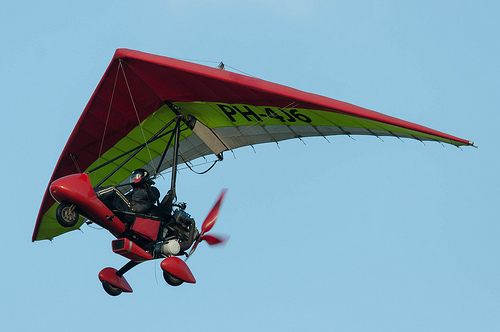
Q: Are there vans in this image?
A: No, there are no vans.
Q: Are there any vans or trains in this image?
A: No, there are no vans or trains.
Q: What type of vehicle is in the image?
A: The vehicle is a car.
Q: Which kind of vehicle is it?
A: The vehicle is a car.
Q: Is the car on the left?
A: Yes, the car is on the left of the image.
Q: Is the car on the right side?
A: No, the car is on the left of the image.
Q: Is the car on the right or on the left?
A: The car is on the left of the image.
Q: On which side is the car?
A: The car is on the left of the image.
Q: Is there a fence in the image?
A: No, there are no fences.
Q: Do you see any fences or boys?
A: No, there are no fences or boys.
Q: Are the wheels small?
A: Yes, the wheels are small.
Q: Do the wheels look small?
A: Yes, the wheels are small.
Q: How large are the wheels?
A: The wheels are small.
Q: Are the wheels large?
A: No, the wheels are small.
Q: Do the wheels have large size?
A: No, the wheels are small.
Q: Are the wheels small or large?
A: The wheels are small.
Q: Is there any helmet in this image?
A: Yes, there is a helmet.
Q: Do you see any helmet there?
A: Yes, there is a helmet.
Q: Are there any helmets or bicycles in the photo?
A: Yes, there is a helmet.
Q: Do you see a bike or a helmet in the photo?
A: Yes, there is a helmet.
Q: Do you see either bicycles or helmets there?
A: Yes, there is a helmet.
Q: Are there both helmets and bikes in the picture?
A: No, there is a helmet but no bikes.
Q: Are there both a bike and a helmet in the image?
A: No, there is a helmet but no bikes.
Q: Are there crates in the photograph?
A: No, there are no crates.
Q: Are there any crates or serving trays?
A: No, there are no crates or serving trays.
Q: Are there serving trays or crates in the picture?
A: No, there are no crates or serving trays.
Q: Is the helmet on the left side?
A: Yes, the helmet is on the left of the image.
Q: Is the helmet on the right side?
A: No, the helmet is on the left of the image.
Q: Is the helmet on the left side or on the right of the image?
A: The helmet is on the left of the image.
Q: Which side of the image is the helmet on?
A: The helmet is on the left of the image.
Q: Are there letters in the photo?
A: Yes, there are letters.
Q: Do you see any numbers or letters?
A: Yes, there are letters.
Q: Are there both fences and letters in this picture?
A: No, there are letters but no fences.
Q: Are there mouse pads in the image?
A: No, there are no mouse pads.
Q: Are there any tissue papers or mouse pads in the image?
A: No, there are no mouse pads or tissue papers.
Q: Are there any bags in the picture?
A: No, there are no bags.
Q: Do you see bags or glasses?
A: No, there are no bags or glasses.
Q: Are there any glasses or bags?
A: No, there are no bags or glasses.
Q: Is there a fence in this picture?
A: No, there are no fences.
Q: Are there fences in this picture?
A: No, there are no fences.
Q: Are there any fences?
A: No, there are no fences.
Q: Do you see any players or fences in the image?
A: No, there are no fences or players.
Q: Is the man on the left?
A: Yes, the man is on the left of the image.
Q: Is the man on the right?
A: No, the man is on the left of the image.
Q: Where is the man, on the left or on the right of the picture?
A: The man is on the left of the image.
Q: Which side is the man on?
A: The man is on the left of the image.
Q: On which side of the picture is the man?
A: The man is on the left of the image.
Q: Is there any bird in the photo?
A: No, there are no birds.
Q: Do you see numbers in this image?
A: Yes, there are numbers.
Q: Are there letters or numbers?
A: Yes, there are numbers.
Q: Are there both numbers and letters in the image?
A: Yes, there are both numbers and letters.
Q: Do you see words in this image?
A: No, there are no words.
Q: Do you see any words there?
A: No, there are no words.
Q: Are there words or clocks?
A: No, there are no words or clocks.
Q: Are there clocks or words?
A: No, there are no words or clocks.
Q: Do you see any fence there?
A: No, there are no fences.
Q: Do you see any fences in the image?
A: No, there are no fences.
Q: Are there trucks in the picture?
A: No, there are no trucks.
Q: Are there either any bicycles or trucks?
A: No, there are no trucks or bicycles.